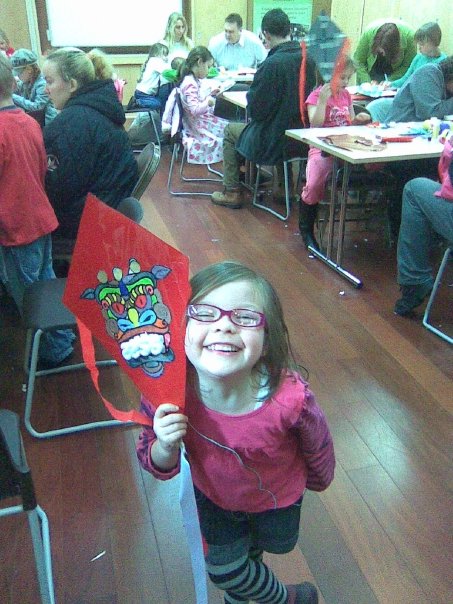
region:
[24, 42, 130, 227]
a person is sitting down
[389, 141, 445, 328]
a person is sitting down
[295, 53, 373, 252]
a person is sitting down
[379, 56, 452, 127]
a person is sitting down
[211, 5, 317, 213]
a person is sitting down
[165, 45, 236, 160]
a person is sitting down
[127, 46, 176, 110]
a person is sitting down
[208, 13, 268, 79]
a person is sitting down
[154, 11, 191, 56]
a person is sitting down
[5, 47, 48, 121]
a person is sitting down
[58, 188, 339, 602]
Little girl holding a red kite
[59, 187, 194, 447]
Kite is red and small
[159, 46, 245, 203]
Little girl sitting on a chair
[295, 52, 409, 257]
Little girl sitting on a chair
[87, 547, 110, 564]
trash on the floor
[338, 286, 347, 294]
trash on the floor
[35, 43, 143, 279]
Woman wearing a hoodie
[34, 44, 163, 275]
Woman wearing hoodie sitting on a chair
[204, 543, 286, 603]
Girl wearing striped leggings on legs.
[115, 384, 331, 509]
Girl wearing pink shirt.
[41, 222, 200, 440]
Girl holding red kite in hand.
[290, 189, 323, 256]
Person wearing black tall boots.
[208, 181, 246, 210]
Person wearing brown boot.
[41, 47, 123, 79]
Woman's hair is pulled back in pony tail.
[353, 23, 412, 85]
Person wearing bright green shirt.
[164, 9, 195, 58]
Woman has long blonde hair.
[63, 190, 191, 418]
red kite with monster face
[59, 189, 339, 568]
small child holding red kite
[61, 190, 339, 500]
little girl smiling holding kite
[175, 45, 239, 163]
girl in floral dress reading book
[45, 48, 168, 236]
woman in black coat sitting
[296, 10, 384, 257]
girl in pink holding kite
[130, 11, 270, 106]
man and woman watching little girl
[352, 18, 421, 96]
woman in green jacket leaning over table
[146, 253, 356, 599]
A small girl.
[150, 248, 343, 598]
A girl wearing glasses.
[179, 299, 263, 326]
A pair of purple framed glasses.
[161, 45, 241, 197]
A girl sitting in a chair.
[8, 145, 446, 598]
Hardwood flooring.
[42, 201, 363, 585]
A girl holding up a kite.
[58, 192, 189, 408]
A red kite with a design in the middle of it.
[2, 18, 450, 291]
People sitting at a table.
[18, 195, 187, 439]
A black and grey chair.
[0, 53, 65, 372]
A person wearing a red shirt.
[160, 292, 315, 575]
A little girl with glasses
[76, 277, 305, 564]
A little girl holding a flag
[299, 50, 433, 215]
A little girl making a flag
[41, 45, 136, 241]
A woman in a black jacket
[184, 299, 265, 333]
A girl wearing pink eye glasses.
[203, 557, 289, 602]
A girl wearing striped pants.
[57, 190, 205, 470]
A girl holding a kite inside of her hands.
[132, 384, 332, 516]
A girl wearing a pink shirt.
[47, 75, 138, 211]
A woman wearing a black jacket.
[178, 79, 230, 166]
A girl wearing a flowered dress.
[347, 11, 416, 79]
A woman wearing a green jacket bending over.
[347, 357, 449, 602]
The floor is made of hardwood.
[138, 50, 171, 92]
A little girl wearing a white shirt.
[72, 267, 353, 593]
Girl holding red kite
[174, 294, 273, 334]
pink glasses on girl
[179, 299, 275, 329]
pink glasses on girl